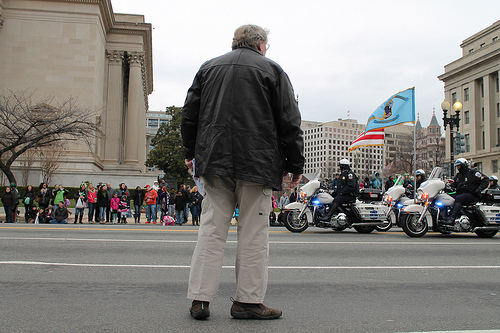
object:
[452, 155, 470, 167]
helmet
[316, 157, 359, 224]
man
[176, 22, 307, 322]
man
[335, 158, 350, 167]
helmet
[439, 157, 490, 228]
cop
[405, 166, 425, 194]
cop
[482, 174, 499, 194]
cop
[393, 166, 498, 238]
motorcycle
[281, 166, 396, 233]
motorcycle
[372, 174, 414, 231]
motorcycle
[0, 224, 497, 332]
street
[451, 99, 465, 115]
streetlamp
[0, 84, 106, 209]
tree